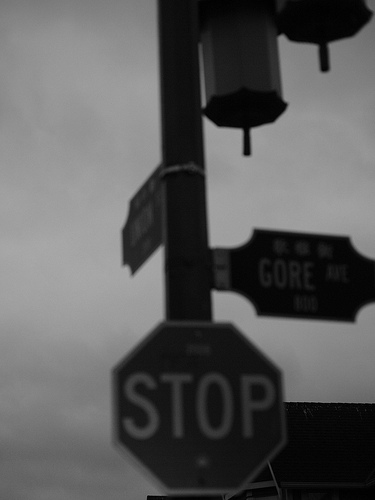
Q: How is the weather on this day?
A: It is cloudy.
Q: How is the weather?
A: It is cloudy.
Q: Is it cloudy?
A: Yes, it is cloudy.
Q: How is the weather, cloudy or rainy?
A: It is cloudy.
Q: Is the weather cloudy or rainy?
A: It is cloudy.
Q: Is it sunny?
A: No, it is cloudy.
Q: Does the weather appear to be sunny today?
A: No, it is cloudy.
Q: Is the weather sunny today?
A: No, it is cloudy.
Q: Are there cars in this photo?
A: No, there are no cars.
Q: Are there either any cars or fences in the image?
A: No, there are no cars or fences.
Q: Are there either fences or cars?
A: No, there are no cars or fences.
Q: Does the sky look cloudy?
A: Yes, the sky is cloudy.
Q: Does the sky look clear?
A: No, the sky is cloudy.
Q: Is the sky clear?
A: No, the sky is cloudy.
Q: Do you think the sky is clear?
A: No, the sky is cloudy.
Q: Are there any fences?
A: No, there are no fences.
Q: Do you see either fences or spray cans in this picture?
A: No, there are no fences or spray cans.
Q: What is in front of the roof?
A: The pole is in front of the roof.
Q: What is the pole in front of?
A: The pole is in front of the roof.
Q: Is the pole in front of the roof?
A: Yes, the pole is in front of the roof.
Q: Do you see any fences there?
A: No, there are no fences.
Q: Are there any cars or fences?
A: No, there are no fences or cars.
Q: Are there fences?
A: No, there are no fences.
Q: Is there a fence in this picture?
A: No, there are no fences.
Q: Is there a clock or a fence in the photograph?
A: No, there are no fences or clocks.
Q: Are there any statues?
A: No, there are no statues.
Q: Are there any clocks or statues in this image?
A: No, there are no statues or clocks.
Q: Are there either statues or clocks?
A: No, there are no statues or clocks.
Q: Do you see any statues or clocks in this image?
A: No, there are no statues or clocks.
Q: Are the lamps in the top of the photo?
A: Yes, the lamps are in the top of the image.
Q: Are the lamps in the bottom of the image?
A: No, the lamps are in the top of the image.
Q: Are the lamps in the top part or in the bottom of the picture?
A: The lamps are in the top of the image.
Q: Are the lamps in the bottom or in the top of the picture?
A: The lamps are in the top of the image.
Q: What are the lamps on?
A: The lamps are on the pole.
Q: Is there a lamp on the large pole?
A: Yes, there are lamps on the pole.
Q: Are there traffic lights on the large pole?
A: No, there are lamps on the pole.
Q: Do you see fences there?
A: No, there are no fences.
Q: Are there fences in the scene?
A: No, there are no fences.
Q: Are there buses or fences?
A: No, there are no fences or buses.